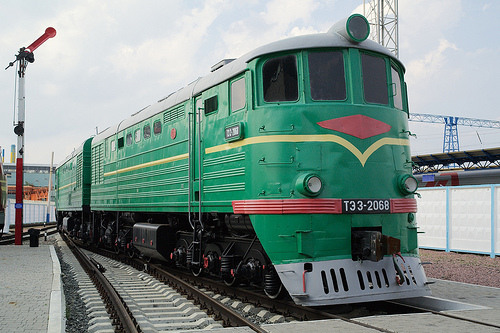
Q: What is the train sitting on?
A: The tracks.